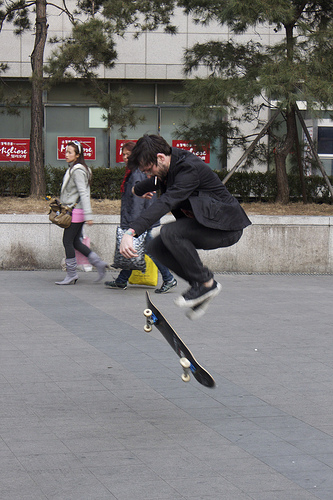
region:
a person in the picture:
[47, 130, 113, 293]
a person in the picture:
[108, 140, 159, 299]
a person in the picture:
[117, 127, 252, 320]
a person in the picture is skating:
[112, 111, 247, 397]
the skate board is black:
[137, 287, 224, 420]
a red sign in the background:
[0, 135, 32, 159]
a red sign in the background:
[50, 134, 96, 163]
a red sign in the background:
[111, 136, 149, 165]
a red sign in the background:
[168, 132, 213, 162]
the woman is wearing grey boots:
[55, 246, 126, 301]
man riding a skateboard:
[107, 129, 274, 395]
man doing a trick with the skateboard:
[98, 97, 245, 410]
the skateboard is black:
[132, 292, 230, 412]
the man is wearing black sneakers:
[156, 267, 222, 319]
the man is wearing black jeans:
[128, 222, 260, 283]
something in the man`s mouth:
[147, 170, 161, 190]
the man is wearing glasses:
[121, 140, 160, 178]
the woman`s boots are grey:
[47, 248, 106, 290]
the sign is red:
[2, 133, 30, 165]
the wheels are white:
[133, 307, 191, 381]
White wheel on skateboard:
[142, 305, 151, 316]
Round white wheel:
[143, 307, 152, 317]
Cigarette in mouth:
[154, 174, 158, 186]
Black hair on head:
[123, 130, 173, 180]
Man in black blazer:
[116, 130, 253, 322]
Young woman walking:
[44, 137, 110, 286]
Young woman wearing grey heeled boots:
[53, 250, 111, 287]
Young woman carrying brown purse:
[47, 140, 111, 285]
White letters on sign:
[0, 145, 28, 155]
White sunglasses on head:
[64, 139, 83, 162]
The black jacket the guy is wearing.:
[162, 147, 254, 235]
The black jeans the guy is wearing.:
[138, 219, 243, 283]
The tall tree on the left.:
[3, 0, 117, 197]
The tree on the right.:
[179, 2, 324, 207]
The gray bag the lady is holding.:
[117, 229, 151, 274]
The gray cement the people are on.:
[6, 269, 332, 497]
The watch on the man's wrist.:
[120, 227, 136, 236]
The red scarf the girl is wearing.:
[117, 163, 132, 194]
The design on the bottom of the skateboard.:
[158, 318, 188, 366]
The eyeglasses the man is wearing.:
[140, 162, 157, 176]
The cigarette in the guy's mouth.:
[152, 175, 159, 186]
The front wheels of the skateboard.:
[141, 299, 153, 332]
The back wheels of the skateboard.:
[176, 354, 190, 382]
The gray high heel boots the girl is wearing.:
[52, 254, 106, 286]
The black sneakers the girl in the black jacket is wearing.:
[106, 264, 177, 297]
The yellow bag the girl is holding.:
[121, 251, 158, 288]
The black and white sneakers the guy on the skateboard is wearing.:
[169, 284, 229, 317]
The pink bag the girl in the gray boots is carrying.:
[63, 231, 95, 269]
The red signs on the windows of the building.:
[0, 133, 221, 172]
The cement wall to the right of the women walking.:
[5, 210, 331, 274]